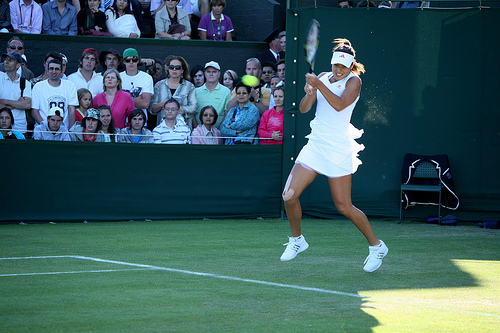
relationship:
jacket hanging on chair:
[398, 151, 458, 211] [397, 150, 447, 221]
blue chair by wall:
[395, 151, 458, 218] [285, 2, 497, 222]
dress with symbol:
[290, 72, 379, 179] [329, 81, 344, 94]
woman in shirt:
[224, 83, 256, 144] [235, 117, 248, 134]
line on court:
[84, 252, 273, 284] [26, 230, 382, 322]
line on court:
[16, 267, 113, 274] [26, 230, 382, 322]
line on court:
[4, 252, 74, 261] [26, 230, 382, 322]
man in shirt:
[29, 58, 81, 129] [28, 79, 80, 128]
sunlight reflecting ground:
[361, 257, 500, 333] [0, 217, 498, 331]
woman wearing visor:
[274, 37, 391, 274] [327, 47, 358, 66]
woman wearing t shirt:
[274, 37, 391, 274] [315, 72, 362, 122]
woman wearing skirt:
[274, 37, 391, 274] [295, 123, 364, 175]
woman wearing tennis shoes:
[289, 37, 389, 282] [263, 231, 405, 276]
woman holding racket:
[274, 37, 391, 274] [301, 15, 323, 91]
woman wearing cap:
[274, 37, 391, 274] [115, 45, 147, 85]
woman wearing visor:
[274, 37, 391, 274] [329, 49, 356, 71]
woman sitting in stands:
[190, 106, 222, 144] [0, 0, 288, 222]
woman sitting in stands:
[224, 83, 256, 144] [0, 0, 288, 222]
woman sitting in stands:
[88, 100, 129, 142] [0, 0, 288, 222]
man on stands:
[115, 107, 152, 142] [0, 0, 288, 222]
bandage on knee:
[282, 170, 292, 202] [282, 187, 292, 200]